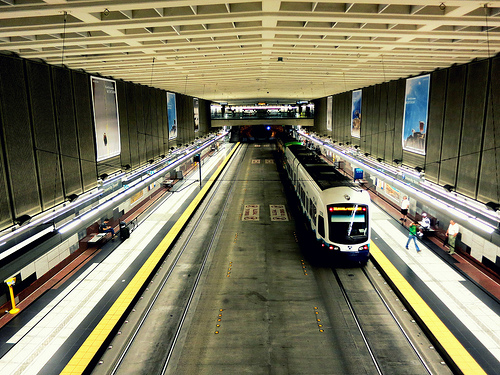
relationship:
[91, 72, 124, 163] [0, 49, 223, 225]
poster hanging on wall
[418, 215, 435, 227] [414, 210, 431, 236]
shirt on person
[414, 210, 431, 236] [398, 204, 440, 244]
person on bench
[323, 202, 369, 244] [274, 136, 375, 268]
windshield on train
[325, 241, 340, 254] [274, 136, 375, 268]
headlight on train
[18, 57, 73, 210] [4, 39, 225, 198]
panel on wall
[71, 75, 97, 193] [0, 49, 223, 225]
panel on wall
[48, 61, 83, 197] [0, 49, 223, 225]
panel on wall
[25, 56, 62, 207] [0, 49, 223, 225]
panel on wall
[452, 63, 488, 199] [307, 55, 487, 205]
panel on wall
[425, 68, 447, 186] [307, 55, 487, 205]
panel on wall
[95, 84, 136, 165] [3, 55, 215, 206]
panel on wall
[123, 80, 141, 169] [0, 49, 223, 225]
panel on wall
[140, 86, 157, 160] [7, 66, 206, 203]
panel on wall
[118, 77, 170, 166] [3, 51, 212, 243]
panel on wall